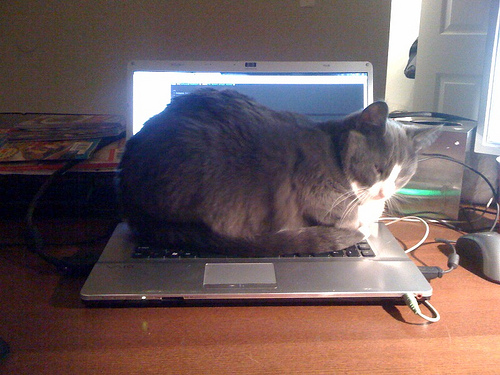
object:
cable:
[23, 145, 106, 275]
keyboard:
[131, 238, 376, 259]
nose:
[376, 188, 388, 199]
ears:
[412, 123, 450, 154]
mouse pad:
[203, 262, 279, 285]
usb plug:
[418, 266, 443, 284]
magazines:
[0, 111, 126, 178]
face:
[349, 139, 416, 201]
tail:
[122, 206, 377, 256]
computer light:
[131, 69, 369, 154]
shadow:
[380, 299, 428, 325]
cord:
[23, 125, 125, 274]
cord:
[401, 293, 440, 323]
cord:
[379, 152, 500, 283]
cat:
[115, 86, 445, 258]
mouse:
[456, 231, 500, 285]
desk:
[0, 212, 500, 375]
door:
[412, 0, 500, 154]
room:
[0, 0, 500, 375]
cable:
[63, 130, 126, 162]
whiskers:
[321, 186, 374, 228]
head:
[340, 100, 445, 208]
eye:
[369, 162, 384, 176]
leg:
[143, 172, 196, 229]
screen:
[131, 70, 367, 137]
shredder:
[383, 109, 477, 222]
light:
[396, 188, 458, 196]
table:
[0, 213, 500, 375]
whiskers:
[385, 188, 422, 218]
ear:
[359, 101, 388, 137]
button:
[166, 249, 181, 258]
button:
[355, 248, 374, 257]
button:
[332, 246, 344, 257]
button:
[340, 243, 357, 258]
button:
[135, 246, 150, 261]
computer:
[79, 58, 434, 308]